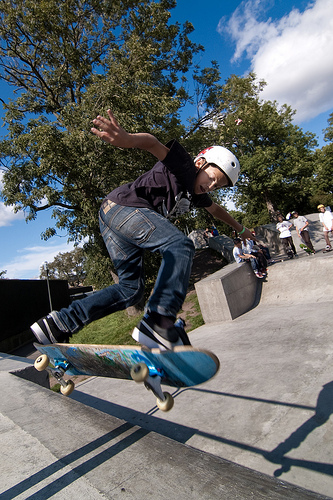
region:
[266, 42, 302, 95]
pat of a cloud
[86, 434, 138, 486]
part of a shade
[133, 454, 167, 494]
part of a floor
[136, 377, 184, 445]
part of a wheel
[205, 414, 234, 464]
part of a shade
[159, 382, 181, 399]
part of a wheel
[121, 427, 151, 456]
par tof a shade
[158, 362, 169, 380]
part of a board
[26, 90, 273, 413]
THE BOY IS SKATING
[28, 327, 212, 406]
the skateboard is blue in colour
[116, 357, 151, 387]
the wheels are brown in colour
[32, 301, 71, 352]
the shoes are black in colour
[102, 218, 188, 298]
the pant is black in colour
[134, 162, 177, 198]
the shirt is brown in colour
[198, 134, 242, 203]
the helmet is white in colour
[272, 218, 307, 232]
the shirts are white in colour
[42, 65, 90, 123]
the tree is green in colour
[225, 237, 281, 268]
the boys are seated on a wall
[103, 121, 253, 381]
MAN DOING TRICK ON SKATEBOARD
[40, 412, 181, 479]
SHADOW OF POLES ON RAMP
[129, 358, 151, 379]
YELLOW WHEEL UNDER SKATEBOARD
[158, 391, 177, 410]
YELLOW WHEEL UNDER SKATEBOARD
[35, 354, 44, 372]
YELLOW WHEEL UNDER SKATEBOARD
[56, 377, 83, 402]
YELLOW WHEEL UNDER SKATEBOARD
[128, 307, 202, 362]
BLACK AND WHITE SHOE ON MAN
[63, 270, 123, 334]
BLUE DENIM JEANS ON SKATER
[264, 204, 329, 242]
SKATERS ON FAR RAMP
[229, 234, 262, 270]
PEOPLE SITTING IN CONCRETE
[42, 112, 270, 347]
this is a man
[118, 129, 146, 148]
the man is light skinned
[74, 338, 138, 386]
this is a skateboard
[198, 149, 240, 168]
this is a helmet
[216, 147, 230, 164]
the helmet is white in color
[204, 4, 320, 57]
this is the sky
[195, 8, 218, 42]
the sky is blue in color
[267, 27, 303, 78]
these are the clouds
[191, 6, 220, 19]
the sky is blue in color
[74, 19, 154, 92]
this is a tree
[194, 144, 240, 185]
white and red helmet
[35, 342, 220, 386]
blue and grey skate board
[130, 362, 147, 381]
grey plastic skate board tire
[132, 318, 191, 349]
black and white sneaker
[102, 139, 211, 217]
blue and cotton tee shirt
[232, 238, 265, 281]
boy sitting on wall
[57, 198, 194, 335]
medium blue denim jeans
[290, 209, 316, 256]
man wearing grey shirt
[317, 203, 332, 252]
person wearing white shirt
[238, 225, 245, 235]
green band on wrist